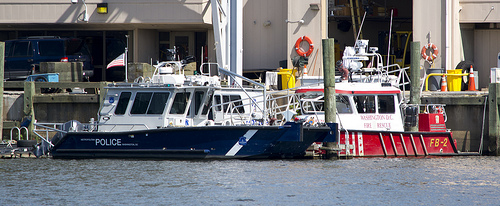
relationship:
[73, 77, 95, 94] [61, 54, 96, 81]
back of car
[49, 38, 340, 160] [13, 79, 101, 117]
blue boat parked at dock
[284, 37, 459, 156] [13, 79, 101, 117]
boat parked at dock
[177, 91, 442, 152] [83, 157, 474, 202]
boardwalk by ocean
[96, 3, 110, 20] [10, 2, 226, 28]
light on wall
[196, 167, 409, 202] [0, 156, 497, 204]
section of ocean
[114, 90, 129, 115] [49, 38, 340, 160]
window on blue boat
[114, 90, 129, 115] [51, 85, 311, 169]
window on side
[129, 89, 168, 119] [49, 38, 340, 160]
window on blue boat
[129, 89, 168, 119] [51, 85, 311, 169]
window on side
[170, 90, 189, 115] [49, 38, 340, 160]
window on blue boat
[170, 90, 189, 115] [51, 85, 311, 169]
window on side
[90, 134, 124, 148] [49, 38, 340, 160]
writing on blue boat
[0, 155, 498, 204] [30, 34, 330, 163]
water next to boat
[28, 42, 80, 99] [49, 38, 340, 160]
car near blue boat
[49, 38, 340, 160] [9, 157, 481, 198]
blue boat in water